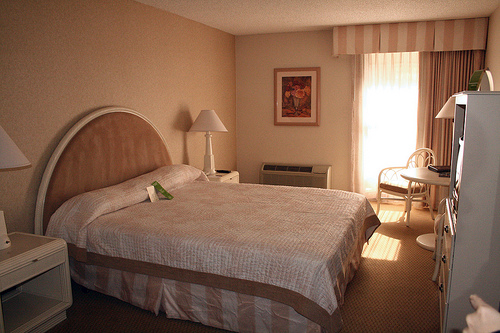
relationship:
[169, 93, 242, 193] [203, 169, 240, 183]
lamp on end table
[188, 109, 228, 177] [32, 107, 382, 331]
lamp near bed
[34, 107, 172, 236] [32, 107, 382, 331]
headboard to bed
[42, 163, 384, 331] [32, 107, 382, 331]
blanket on bed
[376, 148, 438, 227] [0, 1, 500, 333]
chair in bedroom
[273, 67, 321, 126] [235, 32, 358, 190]
painting on wall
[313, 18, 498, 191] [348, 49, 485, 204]
curtain on window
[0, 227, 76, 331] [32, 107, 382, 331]
table next to bed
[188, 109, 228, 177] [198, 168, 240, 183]
lamp on end table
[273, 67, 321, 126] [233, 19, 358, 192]
painting hanging on wall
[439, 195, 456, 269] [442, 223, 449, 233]
drawer has handle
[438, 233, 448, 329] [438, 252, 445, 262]
drawer has handle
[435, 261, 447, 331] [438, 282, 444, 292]
drawer has handle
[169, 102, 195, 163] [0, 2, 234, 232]
shadow on wall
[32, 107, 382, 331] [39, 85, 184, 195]
bed has headboard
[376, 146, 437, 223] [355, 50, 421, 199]
chair next to window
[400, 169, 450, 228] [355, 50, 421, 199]
table next to window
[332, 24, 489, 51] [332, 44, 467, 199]
valance hanging at window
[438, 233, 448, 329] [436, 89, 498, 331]
drawer in a cupboard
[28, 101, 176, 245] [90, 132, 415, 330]
headboard on a bed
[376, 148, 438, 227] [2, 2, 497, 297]
chair in bedroom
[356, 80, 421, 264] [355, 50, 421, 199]
sun shining through window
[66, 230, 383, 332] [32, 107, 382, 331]
dust ruffle part of bed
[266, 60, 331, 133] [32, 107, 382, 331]
ruffle part of bed